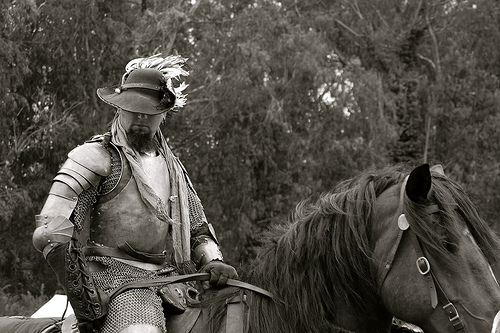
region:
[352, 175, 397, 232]
part of a horse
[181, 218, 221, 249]
part of a metal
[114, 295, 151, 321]
part of a shield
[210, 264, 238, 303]
part of a glove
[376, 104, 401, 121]
part of a forest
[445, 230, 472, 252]
head of a horse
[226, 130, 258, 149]
part of a tree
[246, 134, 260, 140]
part of a bush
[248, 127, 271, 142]
part of a forest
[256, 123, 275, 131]
part of a leaf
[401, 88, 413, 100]
part of a forest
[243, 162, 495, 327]
horse with mane covering eyes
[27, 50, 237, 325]
man in knight armor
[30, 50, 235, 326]
man in hat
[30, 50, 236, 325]
man in armor riding a horse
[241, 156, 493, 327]
horse with dark mane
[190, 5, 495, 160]
trees behind the horse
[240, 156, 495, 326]
horse wearing a saddle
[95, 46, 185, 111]
hat with feathers on top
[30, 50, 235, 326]
bearded man wearing a costume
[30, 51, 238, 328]
man in costume sitting on a horse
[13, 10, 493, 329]
the photograph is black and white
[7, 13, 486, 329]
man on horseback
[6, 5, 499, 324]
man riding a horse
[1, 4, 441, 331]
man wearing armor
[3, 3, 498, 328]
man wearing chain maille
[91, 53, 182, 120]
man wearing a hat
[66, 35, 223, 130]
the hat has feathers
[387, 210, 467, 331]
the bridal on the horse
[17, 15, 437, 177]
trees behind the man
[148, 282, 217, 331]
the leather saddle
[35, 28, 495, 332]
A man is sitting on a horse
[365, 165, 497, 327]
The head of the horse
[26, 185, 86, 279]
The man has his arm bent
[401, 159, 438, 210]
The ear of the horse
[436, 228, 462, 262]
The eye of the horse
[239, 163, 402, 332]
The mane of the horse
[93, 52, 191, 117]
The man is wearing a hat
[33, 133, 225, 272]
The man is wearing armor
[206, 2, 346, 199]
The trees are abundant and tall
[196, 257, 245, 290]
The hand of the man